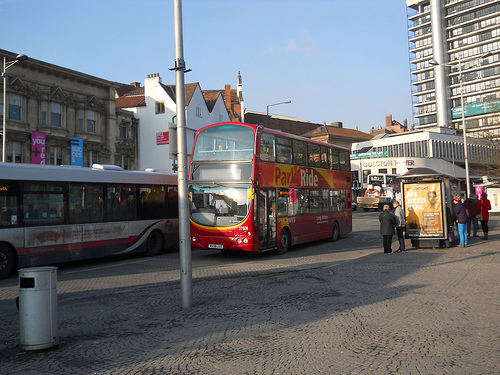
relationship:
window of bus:
[193, 193, 247, 216] [248, 133, 289, 250]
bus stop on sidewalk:
[406, 168, 466, 252] [377, 245, 446, 272]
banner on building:
[22, 118, 59, 165] [25, 58, 67, 123]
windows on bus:
[271, 190, 343, 209] [248, 133, 289, 250]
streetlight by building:
[4, 41, 27, 155] [25, 58, 67, 123]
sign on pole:
[448, 99, 495, 116] [466, 126, 470, 203]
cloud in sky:
[281, 38, 316, 55] [68, 16, 152, 78]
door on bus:
[252, 185, 277, 246] [248, 133, 289, 250]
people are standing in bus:
[98, 194, 142, 221] [0, 165, 182, 260]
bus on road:
[248, 133, 289, 250] [147, 206, 379, 282]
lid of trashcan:
[4, 263, 64, 292] [16, 261, 72, 350]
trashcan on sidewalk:
[16, 261, 72, 350] [377, 245, 446, 272]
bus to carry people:
[248, 133, 289, 250] [287, 193, 335, 217]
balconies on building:
[454, 27, 498, 70] [415, 4, 431, 126]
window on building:
[41, 100, 69, 134] [9, 60, 117, 172]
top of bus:
[253, 123, 350, 165] [248, 133, 289, 250]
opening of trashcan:
[13, 272, 44, 287] [16, 261, 72, 350]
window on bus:
[317, 147, 331, 168] [248, 133, 289, 250]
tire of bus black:
[279, 224, 293, 254] [285, 235, 289, 246]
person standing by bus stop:
[376, 204, 393, 258] [406, 168, 466, 252]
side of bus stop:
[389, 160, 458, 262] [406, 168, 466, 252]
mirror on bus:
[249, 174, 266, 201] [248, 133, 289, 250]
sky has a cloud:
[68, 16, 152, 78] [281, 38, 316, 55]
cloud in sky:
[281, 38, 316, 55] [220, 4, 390, 140]